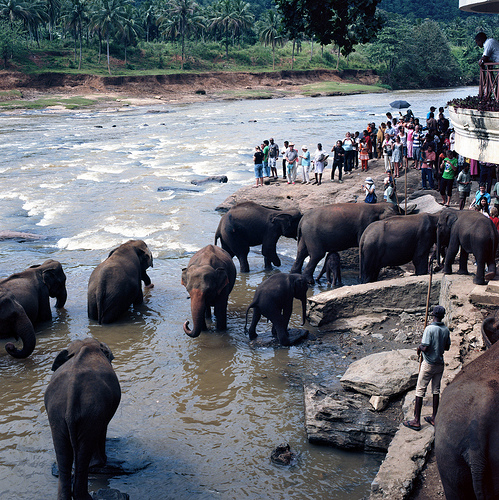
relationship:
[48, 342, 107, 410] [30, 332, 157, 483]
back of elephant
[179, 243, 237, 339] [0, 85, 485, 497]
elephant in river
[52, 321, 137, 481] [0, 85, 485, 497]
elephant in river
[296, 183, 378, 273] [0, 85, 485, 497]
elephant in river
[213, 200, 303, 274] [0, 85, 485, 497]
elephant in river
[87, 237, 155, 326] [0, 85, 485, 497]
elephant in river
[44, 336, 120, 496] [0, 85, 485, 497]
elephant in river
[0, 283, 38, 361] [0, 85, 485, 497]
elephant in river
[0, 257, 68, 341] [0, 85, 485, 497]
elephant in river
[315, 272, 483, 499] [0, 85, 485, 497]
boulders in river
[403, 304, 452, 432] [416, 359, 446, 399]
man wearing pants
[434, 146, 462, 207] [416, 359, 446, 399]
man wearing pants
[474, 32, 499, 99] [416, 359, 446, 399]
man wearing pants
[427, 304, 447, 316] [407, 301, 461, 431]
hair on man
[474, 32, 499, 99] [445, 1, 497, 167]
man outside a building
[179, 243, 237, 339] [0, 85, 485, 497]
elephant bathing in river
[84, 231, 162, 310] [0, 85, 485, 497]
elephant bathing in river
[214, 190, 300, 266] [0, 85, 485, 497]
elephant bathing in river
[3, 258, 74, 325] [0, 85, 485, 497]
elephant bathing in river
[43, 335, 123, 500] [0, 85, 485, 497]
elephant in river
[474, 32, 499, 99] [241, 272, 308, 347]
man watching elephant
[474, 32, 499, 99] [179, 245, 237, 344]
man watching elephant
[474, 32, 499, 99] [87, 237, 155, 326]
man watching elephant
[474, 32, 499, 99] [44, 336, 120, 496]
man watching elephant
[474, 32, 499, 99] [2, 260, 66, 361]
man watching elephant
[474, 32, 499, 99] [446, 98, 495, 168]
man watching from balcony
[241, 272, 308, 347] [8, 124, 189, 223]
elephant in river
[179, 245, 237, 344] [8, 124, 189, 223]
elephant in river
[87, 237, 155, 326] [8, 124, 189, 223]
elephant in river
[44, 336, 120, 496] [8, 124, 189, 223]
elephant in river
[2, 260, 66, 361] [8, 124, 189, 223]
elephant in river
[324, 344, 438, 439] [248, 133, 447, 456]
rock on bank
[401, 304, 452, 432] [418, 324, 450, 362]
man in shirt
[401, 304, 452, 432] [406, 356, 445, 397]
man in pants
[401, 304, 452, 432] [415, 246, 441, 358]
man with pole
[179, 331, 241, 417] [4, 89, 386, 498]
reflection in water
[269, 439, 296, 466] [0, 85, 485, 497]
boulders in river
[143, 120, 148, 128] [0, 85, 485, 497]
rock in river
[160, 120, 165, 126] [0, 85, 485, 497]
rock in river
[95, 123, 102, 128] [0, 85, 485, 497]
rock in river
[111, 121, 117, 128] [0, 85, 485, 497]
rock in river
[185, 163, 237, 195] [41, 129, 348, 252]
rock in rapids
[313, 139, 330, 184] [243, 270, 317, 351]
person looking at elephant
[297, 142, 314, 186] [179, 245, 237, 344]
person looking at elephant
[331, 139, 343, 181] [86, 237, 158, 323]
person looking at elephant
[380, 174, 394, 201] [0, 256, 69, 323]
person looking at elephant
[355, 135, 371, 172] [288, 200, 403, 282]
person looking at elephant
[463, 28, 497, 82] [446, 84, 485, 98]
man on balcony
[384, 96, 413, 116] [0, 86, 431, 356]
rock in river